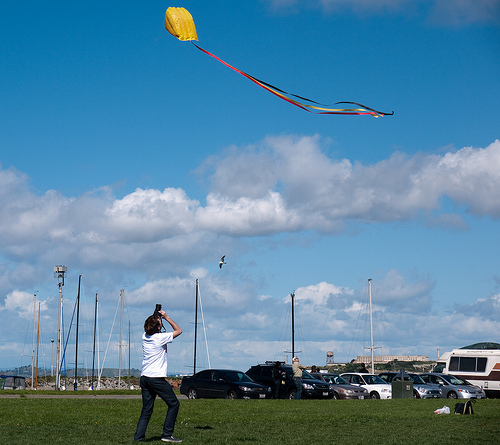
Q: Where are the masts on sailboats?
A: Lower left background.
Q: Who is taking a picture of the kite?
A: Person in white shirt and dark gray pants.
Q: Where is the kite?
A: In the sky.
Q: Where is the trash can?
A: In front of small white car.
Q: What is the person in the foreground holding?
A: Black camera.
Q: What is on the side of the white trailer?
A: Brown stripes.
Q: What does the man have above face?
A: A camera.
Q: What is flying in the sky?
A: Kite.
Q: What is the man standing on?
A: Grass.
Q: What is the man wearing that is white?
A: T shirt.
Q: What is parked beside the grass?
A: Cars.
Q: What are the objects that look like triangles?
A: Sails.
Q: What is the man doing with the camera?
A: Taking a picture.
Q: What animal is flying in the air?
A: Seagull.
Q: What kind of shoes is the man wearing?
A: Tennis shoes.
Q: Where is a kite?
A: In air.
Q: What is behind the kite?
A: Tails.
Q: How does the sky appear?
A: Cloudy.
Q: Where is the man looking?
A: Up at kite.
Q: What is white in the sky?
A: Clouds.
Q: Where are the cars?
A: Parking lot.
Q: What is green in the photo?
A: Grass.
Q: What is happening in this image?
A: A man is taking a picture of a kite.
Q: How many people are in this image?
A: Two.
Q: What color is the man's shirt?
A: White.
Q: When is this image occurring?
A: During the day.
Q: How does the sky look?
A: Cloudy and blue.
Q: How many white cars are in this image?
A: 2.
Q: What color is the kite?
A: Yellow.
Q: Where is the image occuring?
A: In a field.